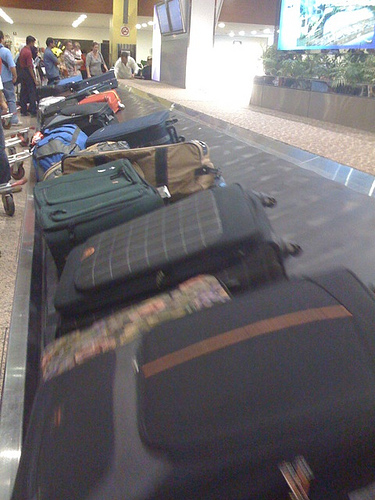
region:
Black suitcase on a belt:
[34, 257, 365, 498]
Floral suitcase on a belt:
[38, 268, 250, 381]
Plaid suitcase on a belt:
[42, 206, 294, 297]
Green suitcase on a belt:
[26, 165, 173, 265]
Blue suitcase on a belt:
[86, 106, 208, 163]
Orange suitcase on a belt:
[80, 88, 128, 115]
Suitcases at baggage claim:
[43, 238, 374, 493]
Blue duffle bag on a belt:
[26, 118, 112, 172]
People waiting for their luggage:
[20, 29, 135, 80]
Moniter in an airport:
[148, 1, 196, 34]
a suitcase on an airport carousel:
[30, 263, 369, 495]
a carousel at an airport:
[29, 55, 368, 489]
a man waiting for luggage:
[16, 27, 43, 114]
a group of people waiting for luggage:
[4, 28, 144, 115]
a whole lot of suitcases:
[28, 73, 374, 481]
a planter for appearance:
[241, 33, 365, 129]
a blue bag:
[19, 125, 93, 168]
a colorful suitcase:
[34, 272, 245, 374]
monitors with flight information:
[146, 2, 202, 38]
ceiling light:
[64, 11, 95, 33]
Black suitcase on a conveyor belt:
[11, 276, 374, 499]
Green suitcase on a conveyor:
[23, 160, 171, 238]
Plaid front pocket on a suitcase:
[75, 186, 221, 289]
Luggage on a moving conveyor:
[15, 75, 373, 495]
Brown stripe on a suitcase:
[135, 304, 360, 376]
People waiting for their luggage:
[0, 26, 142, 118]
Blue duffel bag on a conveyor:
[30, 120, 79, 165]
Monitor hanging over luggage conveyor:
[278, 2, 374, 46]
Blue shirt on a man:
[41, 47, 60, 77]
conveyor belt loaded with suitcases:
[17, 67, 373, 498]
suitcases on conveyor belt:
[14, 67, 372, 497]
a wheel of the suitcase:
[262, 191, 279, 209]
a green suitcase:
[29, 155, 167, 251]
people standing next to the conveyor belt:
[1, 23, 131, 122]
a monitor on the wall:
[153, 1, 188, 37]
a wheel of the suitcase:
[167, 115, 182, 124]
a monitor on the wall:
[271, 1, 373, 52]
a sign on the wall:
[118, 25, 131, 38]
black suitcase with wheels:
[52, 174, 304, 333]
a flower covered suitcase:
[12, 270, 251, 383]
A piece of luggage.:
[18, 323, 342, 484]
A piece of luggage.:
[52, 293, 211, 370]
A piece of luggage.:
[25, 155, 201, 265]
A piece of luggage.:
[40, 134, 258, 211]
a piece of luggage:
[10, 265, 373, 499]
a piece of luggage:
[42, 271, 229, 381]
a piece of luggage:
[54, 183, 300, 333]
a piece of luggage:
[32, 157, 163, 258]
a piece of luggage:
[62, 140, 212, 196]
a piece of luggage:
[84, 110, 183, 146]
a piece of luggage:
[39, 103, 115, 135]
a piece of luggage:
[72, 69, 118, 97]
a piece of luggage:
[33, 123, 86, 172]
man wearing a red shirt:
[17, 36, 40, 115]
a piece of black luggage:
[16, 268, 374, 497]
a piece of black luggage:
[53, 187, 301, 337]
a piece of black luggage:
[86, 111, 184, 149]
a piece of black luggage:
[41, 104, 117, 133]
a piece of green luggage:
[32, 159, 162, 265]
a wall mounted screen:
[153, 3, 169, 36]